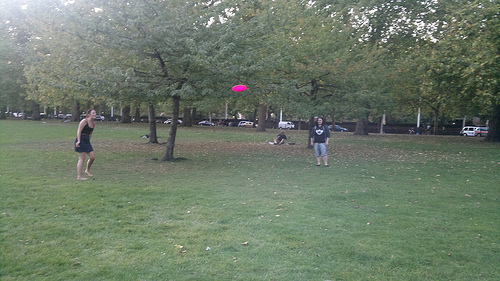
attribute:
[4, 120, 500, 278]
grass — short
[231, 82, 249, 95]
frisbee — pink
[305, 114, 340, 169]
woman — white, standing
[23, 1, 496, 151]
trees — full, thick, green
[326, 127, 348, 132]
car — is blue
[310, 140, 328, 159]
shorts — jean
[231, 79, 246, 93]
frisbee —  pink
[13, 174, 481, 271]
grass —  ground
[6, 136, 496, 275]
grass —  green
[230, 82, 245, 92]
frisbee —  in air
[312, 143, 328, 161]
shorts —  blue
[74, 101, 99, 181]
woman —  barefoot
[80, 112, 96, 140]
top —  tank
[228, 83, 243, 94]
frisbee —  pink,  in air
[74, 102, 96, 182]
girl —  barefoot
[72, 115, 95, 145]
top —  tank,  black 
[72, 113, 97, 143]
shirt —  black 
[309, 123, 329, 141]
shirt —  black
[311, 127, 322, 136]
symbol —  white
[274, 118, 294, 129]
van —  white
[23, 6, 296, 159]
tree —  park's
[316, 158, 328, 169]
shoes —  black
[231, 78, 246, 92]
frisbee —  pink,  in air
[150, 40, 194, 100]
branches —  many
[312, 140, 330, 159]
half-trouser —  blue